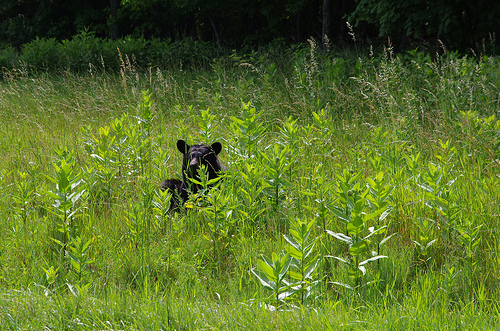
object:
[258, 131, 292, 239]
plant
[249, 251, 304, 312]
green plant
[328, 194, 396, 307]
green plant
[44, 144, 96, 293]
green plant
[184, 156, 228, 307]
green plant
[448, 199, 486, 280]
green plant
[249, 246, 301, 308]
plant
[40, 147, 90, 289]
plant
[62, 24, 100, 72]
plant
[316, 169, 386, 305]
green plant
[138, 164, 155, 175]
green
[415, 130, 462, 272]
plants